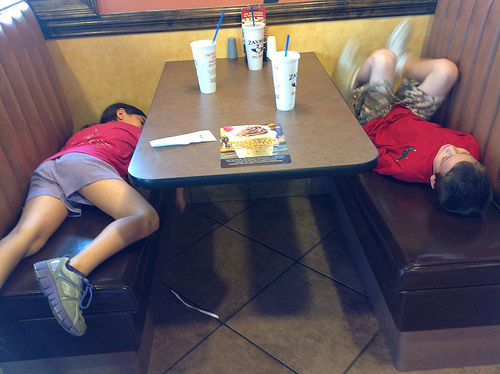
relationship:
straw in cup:
[284, 34, 290, 57] [264, 49, 306, 113]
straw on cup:
[282, 33, 289, 55] [269, 50, 299, 112]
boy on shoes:
[333, 16, 492, 222] [387, 20, 412, 75]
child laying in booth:
[24, 86, 156, 267] [5, 0, 499, 371]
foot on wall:
[331, 37, 363, 97] [39, 4, 437, 166]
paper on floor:
[169, 288, 220, 321] [152, 194, 392, 373]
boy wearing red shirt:
[419, 135, 487, 218] [383, 115, 436, 172]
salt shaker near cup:
[265, 33, 277, 60] [240, 19, 265, 71]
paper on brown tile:
[167, 285, 225, 325] [164, 224, 296, 320]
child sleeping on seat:
[0, 101, 164, 337] [0, 2, 160, 371]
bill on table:
[145, 124, 217, 153] [0, 2, 499, 370]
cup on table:
[241, 17, 268, 71] [127, 50, 377, 354]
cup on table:
[271, 51, 300, 111] [127, 50, 377, 354]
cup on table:
[188, 38, 219, 91] [127, 50, 377, 354]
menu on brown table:
[220, 122, 290, 168] [128, 51, 380, 188]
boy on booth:
[333, 16, 492, 222] [5, 0, 499, 371]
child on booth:
[0, 101, 164, 337] [35, 13, 496, 281]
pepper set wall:
[225, 35, 238, 60] [39, 14, 431, 132]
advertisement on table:
[216, 120, 298, 171] [130, 47, 392, 184]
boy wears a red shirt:
[333, 16, 492, 222] [363, 105, 480, 185]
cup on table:
[241, 20, 265, 70] [159, 53, 390, 253]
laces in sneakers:
[77, 272, 92, 312] [28, 246, 112, 358]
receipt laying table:
[156, 130, 212, 147] [162, 154, 213, 174]